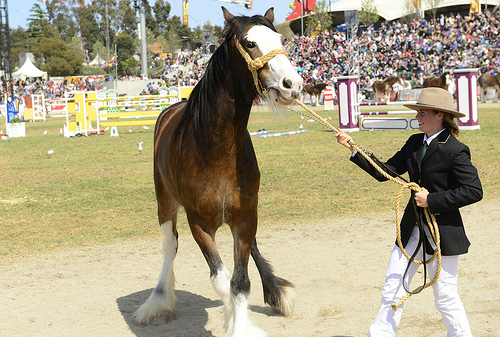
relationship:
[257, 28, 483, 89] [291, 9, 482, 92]
crowd in stands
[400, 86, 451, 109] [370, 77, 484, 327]
hat on woman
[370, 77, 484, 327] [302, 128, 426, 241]
woman has rope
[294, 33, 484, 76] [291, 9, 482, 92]
spectators in stands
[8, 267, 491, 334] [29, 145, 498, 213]
sand next to grass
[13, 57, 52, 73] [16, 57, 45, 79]
tent top white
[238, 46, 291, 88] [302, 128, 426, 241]
halter thick rope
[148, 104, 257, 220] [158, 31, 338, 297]
brown and white horse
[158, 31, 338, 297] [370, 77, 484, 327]
horse pulled by woman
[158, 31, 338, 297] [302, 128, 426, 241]
horse tied to rope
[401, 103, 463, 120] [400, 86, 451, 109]
section of hat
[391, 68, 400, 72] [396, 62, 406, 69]
man has elbow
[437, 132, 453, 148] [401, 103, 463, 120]
black coat section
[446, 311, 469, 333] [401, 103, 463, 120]
trouser has a section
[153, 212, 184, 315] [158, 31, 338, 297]
leg back of horse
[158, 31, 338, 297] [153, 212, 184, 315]
horse has front leg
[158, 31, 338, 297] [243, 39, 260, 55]
horse has eye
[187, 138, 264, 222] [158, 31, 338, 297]
body front of horse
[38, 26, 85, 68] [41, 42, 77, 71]
tree has leaves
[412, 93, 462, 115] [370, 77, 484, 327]
tan hat on woman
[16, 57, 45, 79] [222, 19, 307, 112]
white on horses head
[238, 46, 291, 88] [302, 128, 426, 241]
halter tied by rope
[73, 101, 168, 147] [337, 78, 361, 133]
obstacles for fence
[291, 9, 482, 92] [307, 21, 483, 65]
stands has audience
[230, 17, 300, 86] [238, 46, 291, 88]
head has halter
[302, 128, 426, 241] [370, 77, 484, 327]
rope held by woman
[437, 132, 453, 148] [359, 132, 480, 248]
black riding jacket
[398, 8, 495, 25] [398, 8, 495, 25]
scaffold of scaffold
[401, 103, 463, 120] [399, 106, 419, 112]
brim of hat wide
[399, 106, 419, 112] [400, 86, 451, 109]
wide brim of hat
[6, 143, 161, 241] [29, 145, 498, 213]
arena part grassy